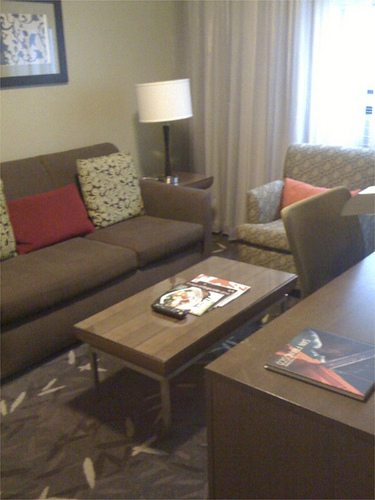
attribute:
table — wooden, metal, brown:
[59, 242, 275, 422]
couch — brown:
[6, 128, 201, 355]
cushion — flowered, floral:
[89, 108, 130, 263]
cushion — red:
[13, 165, 94, 261]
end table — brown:
[144, 158, 227, 211]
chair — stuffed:
[245, 158, 372, 306]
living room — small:
[4, 8, 368, 498]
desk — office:
[196, 261, 374, 492]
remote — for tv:
[156, 298, 187, 323]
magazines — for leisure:
[169, 275, 243, 313]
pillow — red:
[10, 189, 110, 253]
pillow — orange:
[260, 170, 368, 228]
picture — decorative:
[10, 8, 76, 111]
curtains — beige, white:
[185, 17, 312, 239]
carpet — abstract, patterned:
[15, 342, 204, 498]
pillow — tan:
[75, 154, 147, 224]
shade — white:
[134, 78, 196, 124]